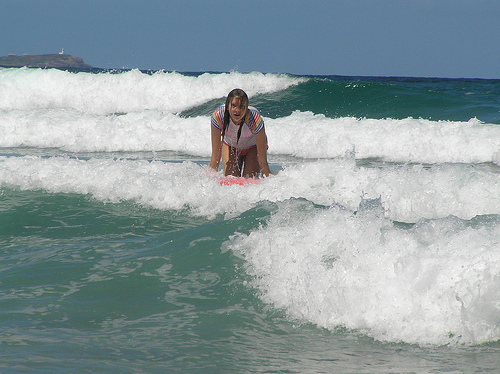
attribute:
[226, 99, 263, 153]
hair — blond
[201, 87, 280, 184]
woman — young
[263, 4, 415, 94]
sky — blue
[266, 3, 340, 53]
sky — blue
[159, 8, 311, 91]
clouds — white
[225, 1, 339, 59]
clouds — white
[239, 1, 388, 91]
clouds — white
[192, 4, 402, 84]
clouds — white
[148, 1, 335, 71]
clouds — white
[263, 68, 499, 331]
water — blue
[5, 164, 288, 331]
water — wavy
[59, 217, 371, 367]
water — blue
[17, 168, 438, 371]
water — wavy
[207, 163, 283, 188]
pink board — pink 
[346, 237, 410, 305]
ocean waves — WHITE , green 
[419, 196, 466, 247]
ocean waves — green , white 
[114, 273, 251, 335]
ocean waves — white , green 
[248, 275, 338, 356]
ocean waves — green , white 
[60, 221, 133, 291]
ocean waves — white , green 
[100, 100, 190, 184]
ocean waves — green , white 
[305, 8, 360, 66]
white clouds — white 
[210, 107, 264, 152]
white shirt — white 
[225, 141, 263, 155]
red trunks — red 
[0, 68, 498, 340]
waves — white  , rushing 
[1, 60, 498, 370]
sea water — blue  , green 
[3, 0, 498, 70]
sky — clear , blue , cloudless 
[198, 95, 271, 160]
shirt — rainbow stripe design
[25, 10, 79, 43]
white clouds — WHITE 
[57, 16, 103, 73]
white clouds — white 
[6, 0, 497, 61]
blue sky — blue 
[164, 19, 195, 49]
white clouds — white 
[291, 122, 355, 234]
waves — white, green, ocean